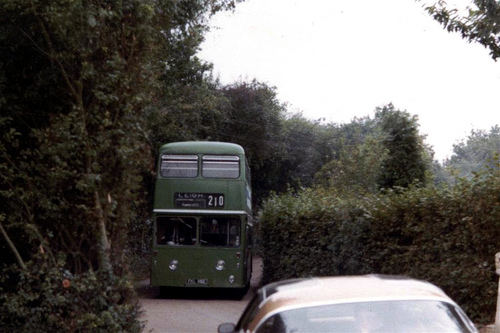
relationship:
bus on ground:
[146, 137, 260, 303] [159, 298, 227, 321]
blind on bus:
[200, 151, 241, 179] [150, 140, 251, 299]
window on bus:
[159, 152, 202, 177] [150, 140, 251, 299]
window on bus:
[195, 215, 240, 248] [150, 140, 251, 299]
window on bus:
[152, 213, 202, 245] [150, 140, 251, 299]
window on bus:
[201, 152, 246, 184] [143, 129, 259, 297]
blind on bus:
[159, 151, 200, 178] [143, 129, 259, 297]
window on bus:
[195, 213, 239, 247] [143, 129, 259, 297]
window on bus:
[153, 212, 199, 247] [143, 129, 259, 297]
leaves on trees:
[350, 165, 378, 188] [268, 74, 478, 279]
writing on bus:
[206, 192, 226, 209] [143, 129, 259, 297]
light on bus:
[215, 257, 228, 271] [143, 129, 259, 297]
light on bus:
[165, 259, 180, 273] [143, 129, 259, 297]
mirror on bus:
[243, 208, 258, 234] [143, 129, 259, 297]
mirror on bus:
[141, 208, 153, 232] [143, 129, 259, 297]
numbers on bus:
[201, 188, 231, 211] [143, 129, 259, 297]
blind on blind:
[163, 152, 198, 174] [159, 151, 200, 178]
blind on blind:
[199, 153, 241, 178] [200, 151, 241, 179]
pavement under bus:
[154, 302, 197, 331] [143, 129, 259, 297]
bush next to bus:
[272, 203, 437, 331] [148, 137, 253, 289]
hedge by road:
[289, 186, 499, 296] [160, 300, 203, 327]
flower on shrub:
[53, 265, 82, 294] [5, 216, 154, 331]